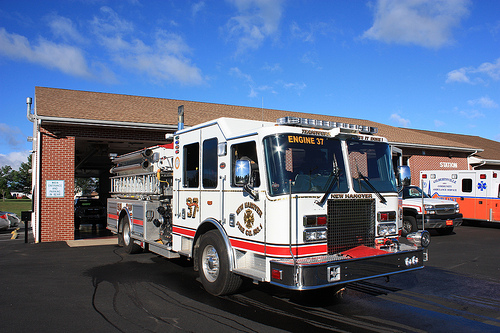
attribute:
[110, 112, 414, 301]
truck — for Firefighting, parked, big, off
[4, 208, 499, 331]
road — black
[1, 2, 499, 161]
sky — puffy, wide, open, big, blue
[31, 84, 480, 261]
building — brown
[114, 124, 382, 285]
ambulance — orange, white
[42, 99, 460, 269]
fire station — brick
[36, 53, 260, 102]
clouds — puffy, white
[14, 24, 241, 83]
clouds — white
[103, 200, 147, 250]
wheel — black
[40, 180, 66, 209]
sign — white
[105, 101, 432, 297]
ambulance — for Fire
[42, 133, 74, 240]
wall —  building's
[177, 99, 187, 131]
pipe — for Exhaust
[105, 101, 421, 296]
engine — for Fire, for  fire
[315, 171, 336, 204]
wipers —  Windshield's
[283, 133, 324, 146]
engine 37 —  in yellow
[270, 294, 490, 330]
streaks —  water's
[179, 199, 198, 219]
37 —  Number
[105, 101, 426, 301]
truck —  with red stripe,  orange and white,  ambulance,  white and silver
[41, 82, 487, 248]
station —  red ,  brick,  for fire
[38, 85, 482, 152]
roof —  brown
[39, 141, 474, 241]
building —  red